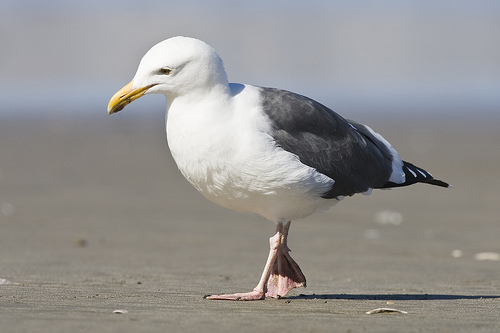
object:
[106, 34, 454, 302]
bird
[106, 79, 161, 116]
beak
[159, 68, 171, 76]
eye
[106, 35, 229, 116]
head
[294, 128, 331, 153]
feather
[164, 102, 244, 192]
chest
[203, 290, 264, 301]
foot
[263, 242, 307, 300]
foot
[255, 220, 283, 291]
leg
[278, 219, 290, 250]
leg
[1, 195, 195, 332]
sand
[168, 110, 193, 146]
feather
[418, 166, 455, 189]
tail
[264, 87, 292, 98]
feather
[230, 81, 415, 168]
back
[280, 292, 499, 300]
shadow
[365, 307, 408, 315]
shell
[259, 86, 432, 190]
wing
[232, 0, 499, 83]
sky